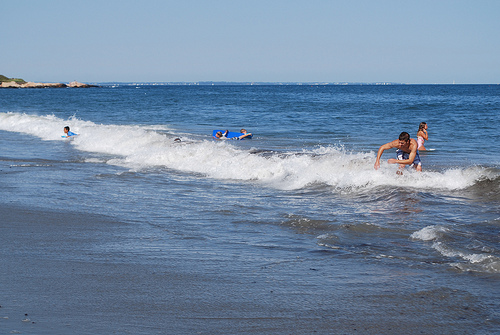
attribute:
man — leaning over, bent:
[375, 131, 422, 175]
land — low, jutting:
[36, 71, 153, 103]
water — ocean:
[2, 82, 497, 334]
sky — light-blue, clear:
[6, 2, 496, 94]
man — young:
[373, 131, 421, 170]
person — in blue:
[64, 124, 73, 134]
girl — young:
[378, 123, 439, 155]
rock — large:
[8, 77, 88, 90]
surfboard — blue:
[211, 127, 243, 138]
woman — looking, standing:
[410, 117, 435, 162]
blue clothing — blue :
[193, 116, 256, 150]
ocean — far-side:
[105, 89, 345, 120]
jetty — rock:
[19, 78, 97, 92]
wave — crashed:
[30, 101, 463, 215]